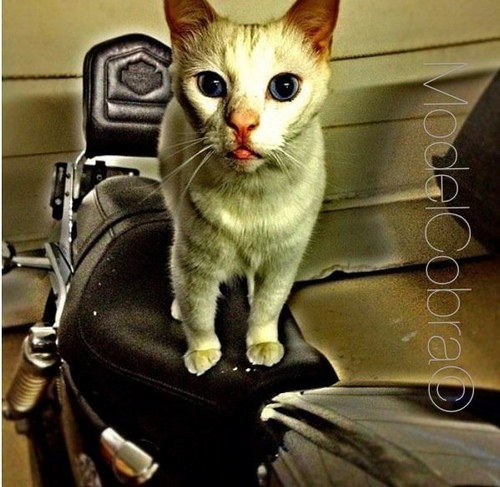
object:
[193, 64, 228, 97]
eyes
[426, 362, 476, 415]
copyright symbol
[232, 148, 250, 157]
tongue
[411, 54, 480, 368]
word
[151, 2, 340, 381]
cat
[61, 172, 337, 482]
seat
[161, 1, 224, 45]
ears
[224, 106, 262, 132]
nose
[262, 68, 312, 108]
left eye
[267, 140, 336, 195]
left side whiskers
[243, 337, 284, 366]
front left paw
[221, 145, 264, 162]
mouth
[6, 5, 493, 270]
wall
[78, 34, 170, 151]
back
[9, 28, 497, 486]
motorcycle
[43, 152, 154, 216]
gas tank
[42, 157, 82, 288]
metal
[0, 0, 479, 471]
photograph